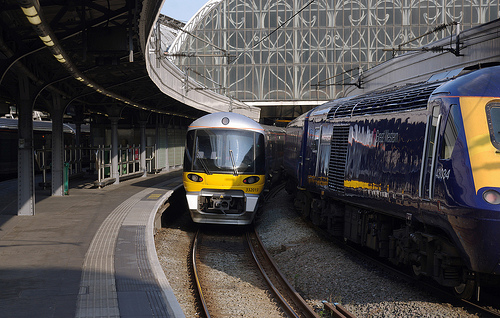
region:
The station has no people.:
[55, 137, 172, 257]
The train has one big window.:
[186, 124, 261, 176]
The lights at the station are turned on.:
[17, 2, 67, 65]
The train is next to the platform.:
[131, 137, 219, 213]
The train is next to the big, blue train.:
[187, 78, 432, 251]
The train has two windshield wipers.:
[192, 127, 245, 178]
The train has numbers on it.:
[235, 172, 267, 197]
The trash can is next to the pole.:
[52, 154, 82, 203]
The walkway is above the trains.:
[180, 2, 434, 107]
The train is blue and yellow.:
[414, 114, 497, 210]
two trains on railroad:
[1, 6, 497, 316]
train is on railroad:
[163, 99, 304, 312]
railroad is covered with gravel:
[153, 232, 382, 317]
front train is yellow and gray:
[179, 110, 270, 234]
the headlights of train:
[185, 167, 262, 188]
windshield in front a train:
[177, 123, 267, 178]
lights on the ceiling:
[21, 4, 181, 120]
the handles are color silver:
[412, 110, 448, 210]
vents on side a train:
[324, 120, 355, 208]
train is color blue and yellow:
[268, 30, 498, 296]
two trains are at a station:
[9, 1, 499, 316]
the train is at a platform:
[182, 112, 287, 244]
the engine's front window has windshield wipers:
[186, 125, 259, 175]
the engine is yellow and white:
[183, 102, 273, 234]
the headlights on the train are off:
[183, 113, 263, 195]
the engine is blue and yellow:
[303, 90, 498, 303]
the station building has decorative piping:
[163, 0, 499, 130]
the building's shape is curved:
[171, 0, 499, 112]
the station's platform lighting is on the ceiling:
[15, 0, 193, 129]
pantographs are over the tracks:
[158, 6, 468, 102]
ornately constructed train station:
[191, 0, 494, 98]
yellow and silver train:
[182, 108, 265, 225]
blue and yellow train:
[283, 62, 498, 307]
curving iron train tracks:
[185, 225, 317, 315]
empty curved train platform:
[1, 92, 191, 303]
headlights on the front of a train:
[183, 165, 263, 188]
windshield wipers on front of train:
[190, 148, 245, 176]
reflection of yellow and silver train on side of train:
[305, 115, 386, 190]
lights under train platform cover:
[17, 2, 75, 70]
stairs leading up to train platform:
[31, 123, 160, 198]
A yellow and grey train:
[185, 102, 286, 237]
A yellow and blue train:
[326, 100, 496, 276]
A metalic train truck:
[169, 219, 221, 302]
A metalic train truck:
[295, 287, 366, 313]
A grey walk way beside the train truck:
[69, 185, 145, 221]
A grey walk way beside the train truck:
[87, 228, 162, 296]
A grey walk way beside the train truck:
[106, 175, 175, 206]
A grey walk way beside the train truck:
[12, 205, 111, 252]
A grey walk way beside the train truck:
[0, 242, 102, 301]